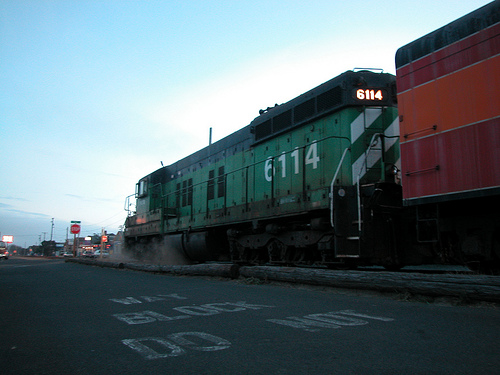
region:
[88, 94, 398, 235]
the train is green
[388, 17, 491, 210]
the container is red and orange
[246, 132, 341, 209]
white numbers on train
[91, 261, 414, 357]
white letters on road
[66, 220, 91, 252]
red sign in road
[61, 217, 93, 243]
the sign is red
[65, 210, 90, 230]
green sign above sign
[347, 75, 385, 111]
orange numbers on train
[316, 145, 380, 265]
steps on side of train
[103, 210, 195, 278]
steam coming from train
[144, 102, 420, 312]
the train is green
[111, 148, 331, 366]
the train is green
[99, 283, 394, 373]
White paint on street saying 'Do not block way'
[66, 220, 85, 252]
Red and white stop sign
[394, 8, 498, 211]
Red, orange and black train car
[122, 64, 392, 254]
Green train engine car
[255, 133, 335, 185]
Number 6114 stenciled on side of train car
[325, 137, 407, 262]
Metal stairs to train car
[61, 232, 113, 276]
Cars waiting for the train to pass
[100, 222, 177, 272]
Smoke from the train engine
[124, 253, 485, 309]
Logs alongside the train tracks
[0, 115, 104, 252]
Blue evening sky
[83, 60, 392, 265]
A green and white train engine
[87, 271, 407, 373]
White letters on black road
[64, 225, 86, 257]
A red and white stop sign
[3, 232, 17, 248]
a shinning sign in the distance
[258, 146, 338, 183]
Number 6114 in white on train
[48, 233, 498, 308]
Logs along side of train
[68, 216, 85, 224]
green street sign above stop sign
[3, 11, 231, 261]
a light blue sky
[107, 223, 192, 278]
dust kicking up from engine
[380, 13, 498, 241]
a red and orange train car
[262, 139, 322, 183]
6114 Numbers on a train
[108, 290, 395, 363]
Large words on the road that say DO NOT BLOCK WAY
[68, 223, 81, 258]
A stop sign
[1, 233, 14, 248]
A lit up sign at the end of the road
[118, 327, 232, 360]
White letters that spell DO on the road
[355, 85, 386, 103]
6114 lit up on a green train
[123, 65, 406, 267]
A green train car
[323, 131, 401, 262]
Railing going up a green train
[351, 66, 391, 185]
Ladder going up a green train